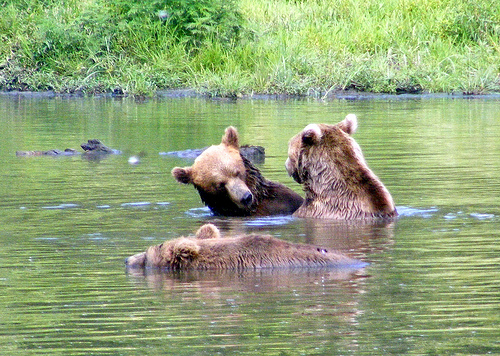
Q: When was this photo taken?
A: During the day.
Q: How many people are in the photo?
A: None.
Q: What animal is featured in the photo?
A: Bears.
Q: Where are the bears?
A: In the water.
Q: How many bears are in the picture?
A: Three.